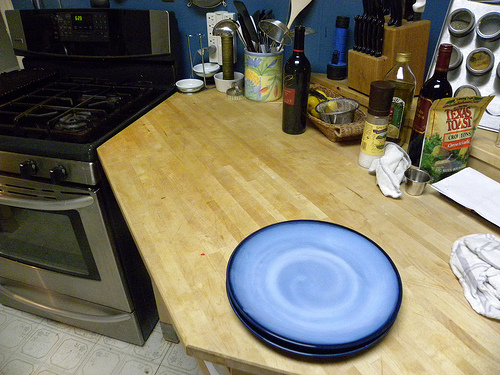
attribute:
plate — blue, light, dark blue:
[225, 221, 401, 348]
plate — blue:
[223, 283, 391, 360]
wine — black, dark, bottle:
[278, 24, 310, 136]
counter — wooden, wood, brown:
[96, 83, 498, 373]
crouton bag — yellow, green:
[416, 94, 495, 182]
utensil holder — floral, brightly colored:
[240, 44, 283, 103]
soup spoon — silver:
[211, 21, 250, 53]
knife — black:
[372, 14, 385, 59]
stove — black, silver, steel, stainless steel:
[1, 10, 177, 349]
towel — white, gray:
[367, 140, 410, 198]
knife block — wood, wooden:
[347, 14, 430, 99]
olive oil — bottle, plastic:
[381, 51, 417, 143]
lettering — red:
[446, 104, 476, 131]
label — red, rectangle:
[284, 86, 297, 107]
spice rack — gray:
[422, 1, 499, 128]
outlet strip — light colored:
[208, 11, 238, 68]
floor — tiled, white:
[4, 306, 203, 374]